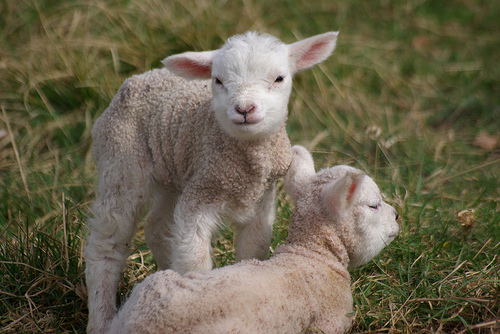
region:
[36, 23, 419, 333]
lamb side by side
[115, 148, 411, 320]
lamb sitting on the ground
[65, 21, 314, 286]
lamb standing up on ground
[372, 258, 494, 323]
mix of green and brown grass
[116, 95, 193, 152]
wool on lamb's body standing up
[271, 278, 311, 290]
wool on lamb's body sitting down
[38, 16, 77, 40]
brown blades of grass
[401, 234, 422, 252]
green blades of grass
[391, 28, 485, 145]
leaves in the ground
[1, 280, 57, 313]
dirt on the ground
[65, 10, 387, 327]
baby sheep in the field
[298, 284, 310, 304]
patch of wool on lamb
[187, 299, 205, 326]
patch of wool on lamb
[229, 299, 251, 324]
patch of wool on lamb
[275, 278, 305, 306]
patch of wool on lamb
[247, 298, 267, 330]
patch of wool on lamb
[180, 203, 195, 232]
patch of wool on lamb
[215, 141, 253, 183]
patch of wool on lamb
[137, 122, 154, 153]
patch of wool on lamb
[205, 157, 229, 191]
patch of wool on lamb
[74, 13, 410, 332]
lambs in the grass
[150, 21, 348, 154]
the face of the white lamb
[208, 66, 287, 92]
the black eyes on the white face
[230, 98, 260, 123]
the nostrils on the lamb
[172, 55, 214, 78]
the pink inner ear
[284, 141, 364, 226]
the ears of the lamb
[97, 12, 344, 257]
the lamb standing up in the grass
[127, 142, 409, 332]
the lamb laying on its belly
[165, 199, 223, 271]
the hair on the legs of the lamb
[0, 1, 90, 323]
the brown grass blades in the grass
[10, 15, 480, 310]
The two sheep are extremely young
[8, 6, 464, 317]
The two sheep were born a week ago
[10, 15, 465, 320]
Two sheep are looking very cute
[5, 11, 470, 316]
Two baby sheep are together today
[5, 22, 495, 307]
The sheep are in some grass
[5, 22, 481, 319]
The sheep are waiting for milk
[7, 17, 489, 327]
The sheep are looking for their mom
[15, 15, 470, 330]
The sheep are wanting to be fed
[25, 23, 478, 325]
The sheep were born on a farm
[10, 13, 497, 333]
The sheep are enjoying the day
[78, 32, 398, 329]
the baby lambs in a field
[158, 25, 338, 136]
the face of the lamb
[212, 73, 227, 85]
the eye of the lamb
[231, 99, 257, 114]
the nose of the lamb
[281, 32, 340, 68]
the ear of the lamb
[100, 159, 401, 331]
a lamb laying in the grass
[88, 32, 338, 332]
a lamb standing in grass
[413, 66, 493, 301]
grass off to the side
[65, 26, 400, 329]
two lambs in grass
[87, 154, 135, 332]
the leg of the lamb